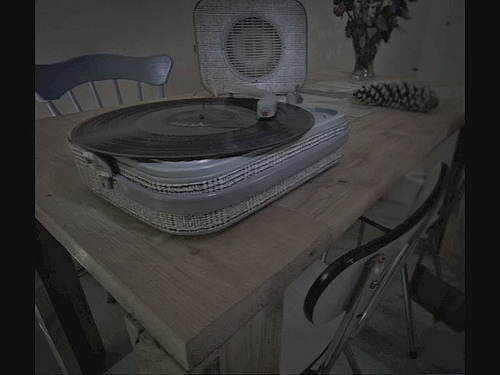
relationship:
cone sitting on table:
[354, 83, 439, 113] [34, 68, 467, 369]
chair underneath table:
[34, 54, 173, 116] [34, 68, 467, 369]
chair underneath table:
[280, 161, 448, 373] [34, 68, 467, 369]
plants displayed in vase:
[334, 1, 413, 69] [348, 27, 389, 82]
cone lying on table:
[354, 83, 439, 113] [34, 68, 467, 369]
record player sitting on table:
[65, 87, 351, 238] [34, 68, 467, 369]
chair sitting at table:
[280, 161, 448, 373] [34, 68, 467, 369]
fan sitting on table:
[194, 0, 308, 97] [34, 68, 467, 369]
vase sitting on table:
[348, 27, 389, 82] [34, 68, 467, 369]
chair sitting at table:
[34, 54, 173, 116] [34, 68, 467, 369]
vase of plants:
[348, 27, 389, 82] [334, 1, 413, 69]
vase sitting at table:
[348, 27, 389, 82] [34, 68, 467, 369]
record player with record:
[65, 87, 351, 238] [67, 96, 315, 160]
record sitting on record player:
[67, 96, 315, 160] [65, 87, 351, 238]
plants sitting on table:
[334, 1, 413, 69] [34, 68, 467, 369]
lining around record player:
[68, 106, 348, 237] [65, 87, 351, 238]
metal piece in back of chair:
[322, 255, 385, 372] [280, 161, 448, 373]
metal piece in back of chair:
[349, 231, 419, 341] [34, 54, 173, 116]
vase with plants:
[348, 27, 389, 82] [334, 1, 413, 69]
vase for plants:
[348, 27, 389, 82] [334, 1, 413, 69]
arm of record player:
[214, 86, 279, 117] [65, 87, 351, 238]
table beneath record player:
[34, 68, 467, 369] [65, 87, 351, 238]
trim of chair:
[305, 162, 450, 324] [280, 161, 448, 373]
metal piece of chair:
[322, 255, 385, 372] [280, 161, 448, 373]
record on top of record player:
[67, 96, 315, 160] [65, 87, 351, 238]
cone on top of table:
[354, 83, 439, 113] [34, 68, 467, 369]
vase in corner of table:
[348, 27, 389, 82] [34, 68, 467, 369]